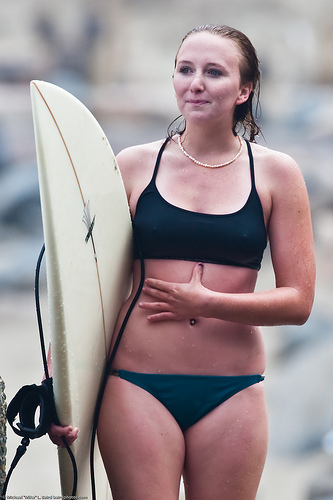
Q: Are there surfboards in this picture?
A: Yes, there is a surfboard.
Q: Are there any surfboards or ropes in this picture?
A: Yes, there is a surfboard.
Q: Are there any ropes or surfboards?
A: Yes, there is a surfboard.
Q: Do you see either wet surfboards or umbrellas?
A: Yes, there is a wet surfboard.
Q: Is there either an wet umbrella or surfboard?
A: Yes, there is a wet surfboard.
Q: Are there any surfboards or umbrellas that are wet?
A: Yes, the surfboard is wet.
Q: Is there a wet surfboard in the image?
A: Yes, there is a wet surfboard.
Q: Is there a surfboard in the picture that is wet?
A: Yes, there is a surfboard that is wet.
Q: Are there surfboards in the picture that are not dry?
A: Yes, there is a wet surfboard.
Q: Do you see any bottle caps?
A: No, there are no bottle caps.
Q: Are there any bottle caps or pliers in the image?
A: No, there are no bottle caps or pliers.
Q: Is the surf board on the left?
A: Yes, the surf board is on the left of the image.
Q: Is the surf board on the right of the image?
A: No, the surf board is on the left of the image.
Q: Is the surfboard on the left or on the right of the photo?
A: The surfboard is on the left of the image.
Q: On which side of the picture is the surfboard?
A: The surfboard is on the left of the image.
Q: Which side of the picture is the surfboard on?
A: The surfboard is on the left of the image.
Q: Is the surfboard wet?
A: Yes, the surfboard is wet.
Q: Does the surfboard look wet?
A: Yes, the surfboard is wet.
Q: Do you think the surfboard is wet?
A: Yes, the surfboard is wet.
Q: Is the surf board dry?
A: No, the surf board is wet.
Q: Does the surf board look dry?
A: No, the surf board is wet.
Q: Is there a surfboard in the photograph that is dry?
A: No, there is a surfboard but it is wet.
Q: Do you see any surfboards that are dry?
A: No, there is a surfboard but it is wet.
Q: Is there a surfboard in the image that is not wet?
A: No, there is a surfboard but it is wet.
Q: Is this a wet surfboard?
A: Yes, this is a wet surfboard.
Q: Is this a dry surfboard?
A: No, this is a wet surfboard.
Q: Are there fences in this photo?
A: No, there are no fences.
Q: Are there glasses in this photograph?
A: No, there are no glasses.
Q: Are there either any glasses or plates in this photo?
A: No, there are no glasses or plates.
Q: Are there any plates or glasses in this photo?
A: No, there are no glasses or plates.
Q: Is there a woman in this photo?
A: Yes, there is a woman.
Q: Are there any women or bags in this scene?
A: Yes, there is a woman.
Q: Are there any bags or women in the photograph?
A: Yes, there is a woman.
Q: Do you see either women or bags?
A: Yes, there is a woman.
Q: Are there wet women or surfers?
A: Yes, there is a wet woman.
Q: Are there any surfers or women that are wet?
A: Yes, the woman is wet.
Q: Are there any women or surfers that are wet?
A: Yes, the woman is wet.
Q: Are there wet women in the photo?
A: Yes, there is a wet woman.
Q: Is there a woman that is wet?
A: Yes, there is a woman that is wet.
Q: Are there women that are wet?
A: Yes, there is a woman that is wet.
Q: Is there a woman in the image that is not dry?
A: Yes, there is a wet woman.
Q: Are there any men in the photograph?
A: No, there are no men.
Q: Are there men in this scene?
A: No, there are no men.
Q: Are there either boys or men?
A: No, there are no men or boys.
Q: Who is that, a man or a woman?
A: That is a woman.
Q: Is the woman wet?
A: Yes, the woman is wet.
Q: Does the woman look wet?
A: Yes, the woman is wet.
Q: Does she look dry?
A: No, the woman is wet.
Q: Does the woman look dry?
A: No, the woman is wet.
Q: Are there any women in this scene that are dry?
A: No, there is a woman but she is wet.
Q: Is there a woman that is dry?
A: No, there is a woman but she is wet.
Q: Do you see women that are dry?
A: No, there is a woman but she is wet.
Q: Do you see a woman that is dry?
A: No, there is a woman but she is wet.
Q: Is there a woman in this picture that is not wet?
A: No, there is a woman but she is wet.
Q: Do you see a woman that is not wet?
A: No, there is a woman but she is wet.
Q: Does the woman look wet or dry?
A: The woman is wet.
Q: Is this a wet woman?
A: Yes, this is a wet woman.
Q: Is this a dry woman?
A: No, this is a wet woman.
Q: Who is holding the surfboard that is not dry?
A: The woman is holding the surfboard.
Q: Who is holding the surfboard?
A: The woman is holding the surfboard.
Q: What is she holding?
A: The woman is holding the surfboard.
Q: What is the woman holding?
A: The woman is holding the surfboard.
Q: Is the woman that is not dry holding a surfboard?
A: Yes, the woman is holding a surfboard.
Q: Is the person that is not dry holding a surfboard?
A: Yes, the woman is holding a surfboard.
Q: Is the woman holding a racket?
A: No, the woman is holding a surfboard.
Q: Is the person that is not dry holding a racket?
A: No, the woman is holding a surfboard.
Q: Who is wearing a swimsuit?
A: The woman is wearing a swimsuit.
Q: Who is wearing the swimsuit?
A: The woman is wearing a swimsuit.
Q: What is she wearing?
A: The woman is wearing a bathing suit.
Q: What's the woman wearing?
A: The woman is wearing a bathing suit.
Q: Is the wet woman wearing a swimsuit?
A: Yes, the woman is wearing a swimsuit.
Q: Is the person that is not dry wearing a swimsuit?
A: Yes, the woman is wearing a swimsuit.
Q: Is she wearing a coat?
A: No, the woman is wearing a swimsuit.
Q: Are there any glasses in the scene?
A: No, there are no glasses.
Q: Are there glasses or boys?
A: No, there are no glasses or boys.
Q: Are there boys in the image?
A: No, there are no boys.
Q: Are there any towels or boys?
A: No, there are no boys or towels.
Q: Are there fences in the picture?
A: No, there are no fences.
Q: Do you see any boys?
A: No, there are no boys.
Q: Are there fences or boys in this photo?
A: No, there are no boys or fences.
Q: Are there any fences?
A: No, there are no fences.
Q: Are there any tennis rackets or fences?
A: No, there are no fences or tennis rackets.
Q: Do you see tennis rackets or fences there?
A: No, there are no fences or tennis rackets.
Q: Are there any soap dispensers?
A: No, there are no soap dispensers.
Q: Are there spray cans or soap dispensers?
A: No, there are no soap dispensers or spray cans.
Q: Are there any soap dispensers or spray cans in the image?
A: No, there are no soap dispensers or spray cans.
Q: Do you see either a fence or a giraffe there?
A: No, there are no fences or giraffes.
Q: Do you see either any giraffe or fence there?
A: No, there are no fences or giraffes.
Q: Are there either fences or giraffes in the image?
A: No, there are no fences or giraffes.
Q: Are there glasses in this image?
A: No, there are no glasses.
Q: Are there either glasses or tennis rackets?
A: No, there are no glasses or tennis rackets.